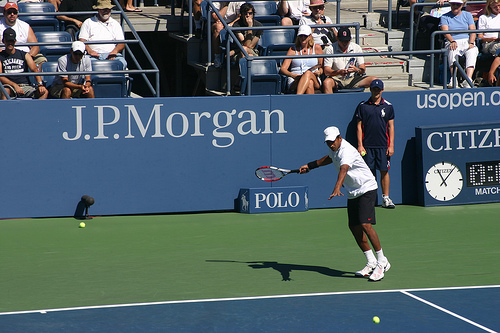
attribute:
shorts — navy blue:
[342, 188, 374, 228]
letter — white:
[190, 110, 212, 138]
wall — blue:
[0, 95, 253, 219]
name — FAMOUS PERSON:
[58, 101, 294, 142]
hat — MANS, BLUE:
[365, 76, 385, 95]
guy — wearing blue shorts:
[353, 77, 399, 210]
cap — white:
[317, 125, 343, 145]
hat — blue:
[364, 78, 387, 88]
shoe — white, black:
[369, 259, 394, 287]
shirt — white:
[325, 136, 376, 200]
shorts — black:
[341, 184, 384, 227]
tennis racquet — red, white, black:
[253, 164, 303, 187]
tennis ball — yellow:
[368, 311, 386, 326]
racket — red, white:
[250, 161, 304, 191]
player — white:
[296, 119, 396, 290]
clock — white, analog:
[422, 159, 465, 206]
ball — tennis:
[70, 212, 90, 230]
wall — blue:
[11, 100, 368, 211]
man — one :
[77, 4, 125, 58]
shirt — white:
[74, 20, 128, 59]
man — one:
[352, 77, 394, 167]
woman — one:
[283, 22, 322, 85]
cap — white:
[291, 20, 311, 40]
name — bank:
[52, 96, 282, 145]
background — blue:
[13, 99, 343, 208]